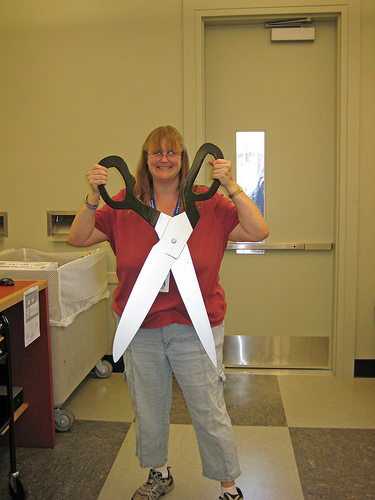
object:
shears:
[91, 139, 225, 372]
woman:
[67, 128, 271, 500]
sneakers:
[133, 471, 185, 498]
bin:
[4, 240, 124, 401]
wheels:
[53, 403, 75, 434]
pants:
[115, 312, 257, 484]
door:
[196, 18, 346, 383]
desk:
[0, 277, 62, 453]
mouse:
[0, 276, 18, 288]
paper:
[19, 290, 48, 348]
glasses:
[151, 148, 177, 159]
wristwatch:
[83, 195, 101, 213]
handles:
[181, 141, 228, 229]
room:
[3, 2, 374, 499]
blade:
[169, 252, 224, 369]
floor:
[45, 365, 373, 499]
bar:
[227, 240, 336, 261]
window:
[231, 123, 269, 226]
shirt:
[98, 181, 234, 327]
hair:
[147, 124, 183, 151]